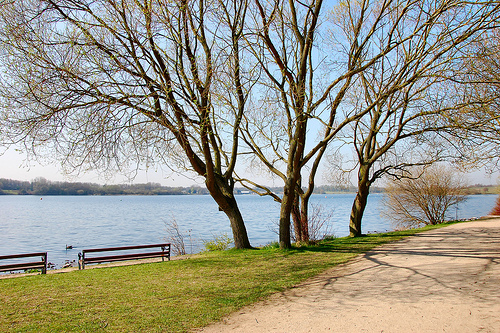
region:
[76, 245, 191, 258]
Park bench near water.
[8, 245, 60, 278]
Park bench near water.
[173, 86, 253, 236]
Large tree near bench.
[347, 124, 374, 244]
Large tree near sidewalk.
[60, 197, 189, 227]
Water in front of benches.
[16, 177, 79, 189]
Many trees in distance.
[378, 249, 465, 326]
Pavement next to grassy area.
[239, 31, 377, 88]
Sky is bright and blue.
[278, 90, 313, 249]
Trees in grassy area near water.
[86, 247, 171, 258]
Bench has wide gape in back.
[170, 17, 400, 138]
the trees are dried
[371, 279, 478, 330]
floor is coverd of sand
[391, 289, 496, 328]
floor is brown in color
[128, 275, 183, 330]
floor is covered of grasses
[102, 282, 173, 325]
floor is green in color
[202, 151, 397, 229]
trees are beside he lake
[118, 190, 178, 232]
water is blue in color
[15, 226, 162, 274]
benches are beside the lake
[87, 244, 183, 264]
the benches are wooden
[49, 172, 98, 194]
the trees fara wy from the lake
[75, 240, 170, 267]
a long wooden bench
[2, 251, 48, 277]
a long wooden bench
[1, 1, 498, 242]
three large trees with no leaves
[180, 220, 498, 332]
a section of concrete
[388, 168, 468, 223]
a bush with no leaves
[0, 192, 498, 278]
a large swath of water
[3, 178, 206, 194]
trees are on a shoreline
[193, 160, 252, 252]
trunk of a tree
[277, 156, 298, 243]
trunk of a tree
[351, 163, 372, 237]
trunk of a tree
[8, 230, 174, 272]
Wooden benches kept near the lake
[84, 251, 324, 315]
Green color grass with dirts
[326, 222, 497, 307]
Shadow of the tree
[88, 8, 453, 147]
Tree with branches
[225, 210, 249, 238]
Bark of the tree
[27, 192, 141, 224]
Small waves in the water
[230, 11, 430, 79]
A blue color sky with clouds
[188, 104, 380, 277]
Green color grass with trees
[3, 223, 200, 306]
Green color grass with wooden benches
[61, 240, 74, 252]
Bird swimming in the water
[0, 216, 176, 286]
two benches in front the ocean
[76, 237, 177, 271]
a bench of wood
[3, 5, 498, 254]
trees in front the water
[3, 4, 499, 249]
trees do not have leaves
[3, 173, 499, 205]
trees on the background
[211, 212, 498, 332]
the road is unpaved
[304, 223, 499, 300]
shadows cast on the road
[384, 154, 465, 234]
a small tree on side the road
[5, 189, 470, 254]
the body of water is blue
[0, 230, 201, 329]
green grass behind two benches